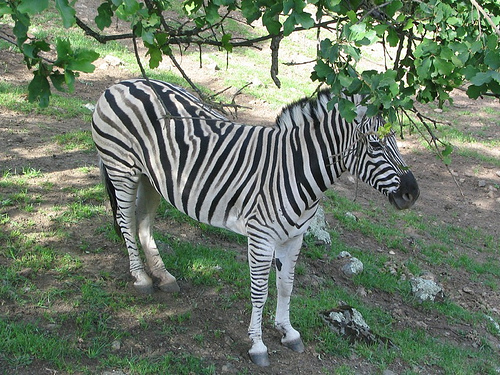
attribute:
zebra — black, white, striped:
[91, 67, 420, 364]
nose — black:
[383, 186, 424, 218]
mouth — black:
[387, 172, 420, 215]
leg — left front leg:
[243, 228, 278, 369]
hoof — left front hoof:
[281, 337, 308, 357]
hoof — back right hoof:
[131, 281, 155, 294]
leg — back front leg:
[93, 130, 151, 287]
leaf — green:
[337, 97, 357, 121]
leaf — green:
[375, 69, 400, 97]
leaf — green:
[315, 41, 333, 63]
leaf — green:
[469, 70, 496, 85]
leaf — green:
[342, 22, 363, 42]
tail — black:
[100, 159, 124, 241]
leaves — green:
[1, 1, 498, 161]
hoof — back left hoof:
[158, 269, 181, 293]